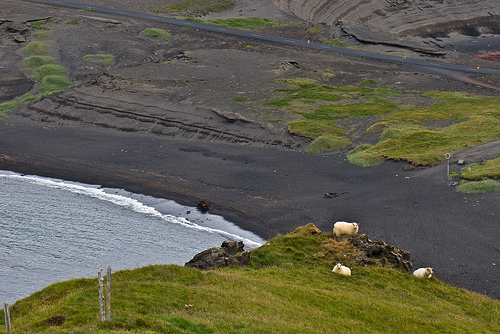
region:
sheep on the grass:
[319, 262, 447, 297]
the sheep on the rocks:
[334, 211, 364, 239]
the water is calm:
[0, 173, 230, 262]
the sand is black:
[1, 69, 406, 223]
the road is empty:
[79, 4, 490, 79]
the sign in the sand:
[439, 151, 463, 175]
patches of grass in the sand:
[289, 78, 402, 128]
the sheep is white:
[328, 215, 365, 234]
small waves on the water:
[0, 169, 222, 251]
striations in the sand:
[56, 95, 176, 146]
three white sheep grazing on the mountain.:
[322, 210, 447, 291]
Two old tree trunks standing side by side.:
[84, 260, 122, 323]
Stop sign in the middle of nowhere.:
[441, 144, 453, 177]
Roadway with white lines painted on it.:
[178, 15, 417, 69]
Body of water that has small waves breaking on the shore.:
[0, 163, 205, 283]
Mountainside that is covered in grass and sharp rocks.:
[2, 227, 498, 329]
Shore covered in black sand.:
[4, 119, 300, 189]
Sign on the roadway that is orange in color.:
[472, 60, 483, 82]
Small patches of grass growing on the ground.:
[270, 69, 498, 152]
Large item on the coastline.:
[188, 196, 213, 217]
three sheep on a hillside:
[322, 210, 448, 291]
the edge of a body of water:
[10, 168, 262, 320]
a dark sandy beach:
[15, 16, 445, 253]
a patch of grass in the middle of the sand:
[279, 74, 486, 169]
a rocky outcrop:
[155, 239, 255, 274]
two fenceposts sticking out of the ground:
[54, 250, 126, 317]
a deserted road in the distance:
[69, 7, 487, 89]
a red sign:
[441, 138, 458, 194]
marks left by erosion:
[30, 62, 264, 174]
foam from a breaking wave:
[27, 177, 259, 244]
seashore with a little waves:
[3, 165, 265, 313]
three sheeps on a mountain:
[330, 216, 431, 282]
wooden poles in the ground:
[95, 263, 115, 324]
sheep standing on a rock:
[330, 217, 356, 237]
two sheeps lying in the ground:
[330, 260, 431, 275]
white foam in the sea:
[1, 170, 256, 246]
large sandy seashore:
[1, 0, 497, 301]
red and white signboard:
[441, 150, 451, 177]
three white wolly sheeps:
[330, 218, 432, 281]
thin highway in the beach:
[38, 0, 499, 76]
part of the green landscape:
[28, 298, 69, 330]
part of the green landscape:
[86, 290, 139, 331]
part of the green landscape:
[158, 293, 195, 330]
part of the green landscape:
[242, 292, 295, 332]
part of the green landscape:
[323, 289, 354, 331]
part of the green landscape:
[397, 297, 427, 332]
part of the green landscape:
[442, 300, 497, 330]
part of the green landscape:
[288, 228, 326, 264]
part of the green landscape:
[258, 248, 280, 273]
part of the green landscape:
[163, 268, 215, 290]